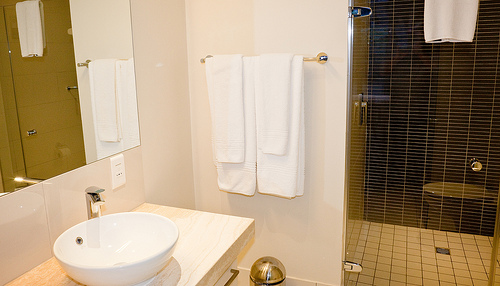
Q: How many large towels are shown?
A: Three.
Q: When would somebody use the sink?
A: When they washed hands.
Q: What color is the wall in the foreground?
A: White.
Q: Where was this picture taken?
A: Bathroom.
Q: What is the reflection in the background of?
A: Toilet.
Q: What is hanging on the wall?
A: A mirror.